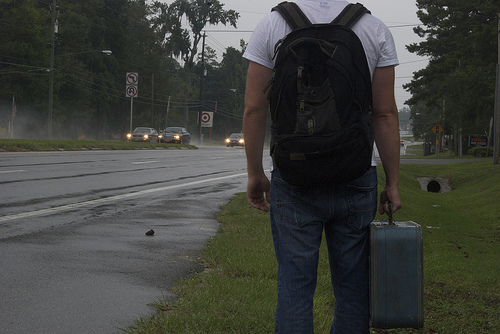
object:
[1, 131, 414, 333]
road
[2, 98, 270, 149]
steam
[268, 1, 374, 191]
backpack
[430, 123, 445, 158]
traffic light  sign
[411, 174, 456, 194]
ditch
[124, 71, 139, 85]
no turn street sign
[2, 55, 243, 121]
electrical lines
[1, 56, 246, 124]
row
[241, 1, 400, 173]
tee shirt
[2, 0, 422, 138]
rain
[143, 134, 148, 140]
headlights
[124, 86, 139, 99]
no u turn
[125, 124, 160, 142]
cars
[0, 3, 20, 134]
trees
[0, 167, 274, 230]
white line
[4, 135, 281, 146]
side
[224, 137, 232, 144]
lights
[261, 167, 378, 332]
denim jeans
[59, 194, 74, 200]
water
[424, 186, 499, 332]
grassy lawn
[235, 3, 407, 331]
man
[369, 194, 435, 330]
luggage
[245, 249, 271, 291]
green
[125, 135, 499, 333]
grass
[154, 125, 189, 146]
traffic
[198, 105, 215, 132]
sign